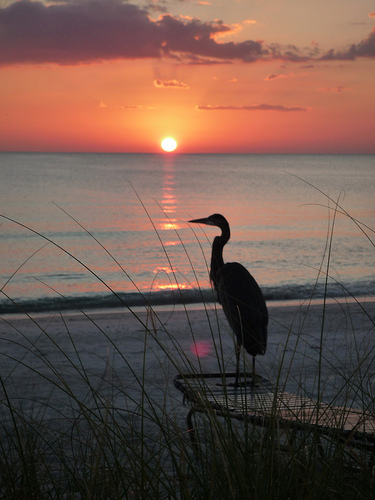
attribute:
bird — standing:
[182, 212, 288, 393]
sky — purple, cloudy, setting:
[1, 0, 374, 154]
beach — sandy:
[0, 302, 374, 499]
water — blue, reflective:
[0, 151, 374, 293]